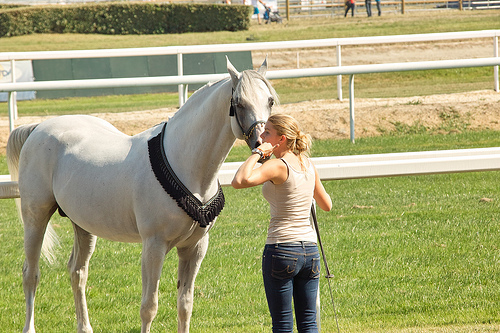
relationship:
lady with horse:
[231, 113, 333, 333] [6, 52, 278, 331]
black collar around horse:
[137, 120, 233, 238] [8, 52, 290, 314]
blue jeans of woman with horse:
[261, 243, 324, 333] [6, 52, 278, 331]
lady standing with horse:
[231, 113, 333, 333] [6, 52, 278, 331]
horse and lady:
[6, 52, 278, 331] [231, 113, 333, 333]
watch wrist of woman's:
[252, 148, 264, 158] [234, 103, 341, 330]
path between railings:
[4, 90, 498, 140] [2, 32, 498, 144]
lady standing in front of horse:
[231, 113, 333, 333] [6, 52, 278, 331]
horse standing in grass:
[6, 52, 278, 331] [8, 139, 497, 329]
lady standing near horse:
[231, 113, 333, 333] [6, 52, 278, 331]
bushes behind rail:
[0, 0, 262, 35] [5, 38, 495, 117]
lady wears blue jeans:
[231, 113, 333, 333] [258, 243, 325, 331]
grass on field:
[364, 227, 466, 282] [1, 165, 497, 330]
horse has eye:
[6, 52, 278, 331] [267, 95, 277, 116]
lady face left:
[231, 113, 333, 333] [13, 5, 62, 326]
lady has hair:
[235, 109, 345, 331] [273, 115, 319, 152]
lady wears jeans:
[231, 113, 333, 333] [267, 229, 361, 320]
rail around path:
[0, 32, 500, 141] [0, 147, 500, 196]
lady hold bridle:
[231, 113, 333, 333] [147, 120, 224, 227]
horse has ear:
[6, 52, 278, 331] [262, 58, 268, 74]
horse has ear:
[6, 52, 278, 331] [224, 52, 242, 87]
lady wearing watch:
[231, 113, 333, 333] [250, 146, 267, 160]